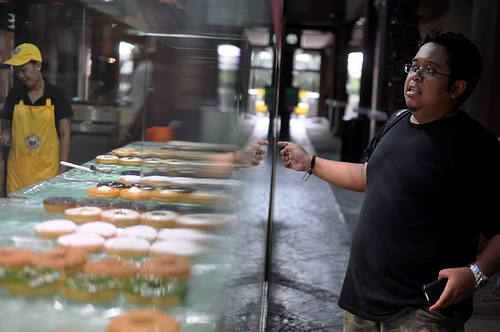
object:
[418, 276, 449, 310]
phone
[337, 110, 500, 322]
tshirt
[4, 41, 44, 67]
cap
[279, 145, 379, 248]
ground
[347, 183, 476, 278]
belly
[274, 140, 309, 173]
hand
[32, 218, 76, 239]
cakes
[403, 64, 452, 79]
glasses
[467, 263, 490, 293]
watch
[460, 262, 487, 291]
wrist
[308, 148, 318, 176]
band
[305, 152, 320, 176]
wrist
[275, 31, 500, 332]
man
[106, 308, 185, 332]
donuts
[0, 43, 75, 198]
person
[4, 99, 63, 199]
apron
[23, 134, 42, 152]
logo